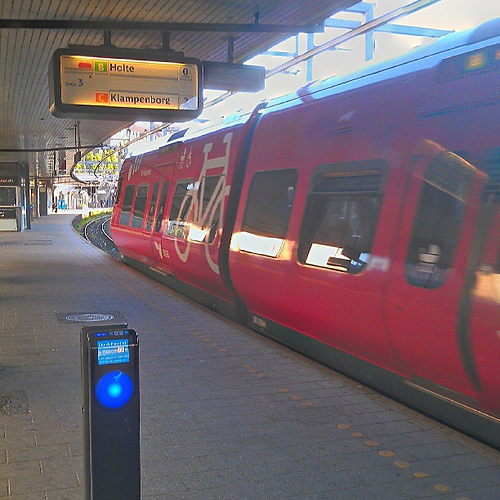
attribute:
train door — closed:
[123, 152, 190, 271]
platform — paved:
[128, 296, 423, 498]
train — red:
[154, 116, 495, 333]